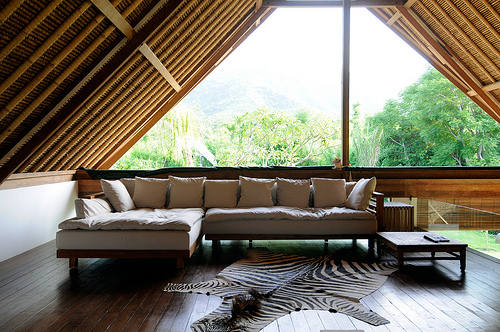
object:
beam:
[342, 0, 349, 166]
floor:
[77, 276, 140, 328]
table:
[375, 231, 468, 283]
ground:
[406, 275, 435, 311]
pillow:
[100, 179, 136, 213]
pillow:
[131, 176, 169, 209]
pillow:
[167, 175, 207, 208]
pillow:
[204, 179, 240, 207]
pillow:
[237, 175, 277, 207]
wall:
[0, 177, 59, 239]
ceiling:
[411, 0, 499, 55]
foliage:
[423, 108, 462, 141]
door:
[51, 0, 113, 152]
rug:
[161, 251, 399, 332]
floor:
[465, 252, 500, 330]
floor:
[4, 252, 59, 313]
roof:
[1, 77, 111, 165]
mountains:
[193, 71, 334, 129]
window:
[95, 0, 497, 170]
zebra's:
[161, 246, 399, 332]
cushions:
[57, 207, 376, 230]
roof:
[436, 0, 496, 70]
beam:
[138, 42, 183, 93]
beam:
[456, 5, 500, 71]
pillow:
[310, 177, 346, 207]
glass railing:
[414, 198, 500, 230]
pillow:
[346, 176, 377, 211]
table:
[369, 201, 415, 232]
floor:
[194, 260, 280, 331]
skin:
[240, 276, 340, 306]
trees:
[374, 70, 494, 172]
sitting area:
[0, 165, 500, 332]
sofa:
[55, 166, 384, 269]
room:
[1, 0, 496, 331]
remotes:
[423, 233, 450, 243]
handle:
[376, 195, 384, 232]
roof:
[0, 0, 246, 47]